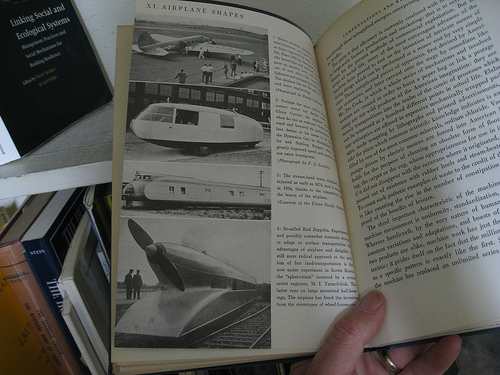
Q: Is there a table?
A: Yes, there is a table.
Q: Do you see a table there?
A: Yes, there is a table.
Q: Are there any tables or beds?
A: Yes, there is a table.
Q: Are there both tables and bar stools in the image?
A: No, there is a table but no bar stools.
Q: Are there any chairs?
A: No, there are no chairs.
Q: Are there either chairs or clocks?
A: No, there are no chairs or clocks.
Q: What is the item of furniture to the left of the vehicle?
A: The piece of furniture is a table.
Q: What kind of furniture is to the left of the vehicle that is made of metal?
A: The piece of furniture is a table.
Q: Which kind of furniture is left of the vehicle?
A: The piece of furniture is a table.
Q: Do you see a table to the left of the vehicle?
A: Yes, there is a table to the left of the vehicle.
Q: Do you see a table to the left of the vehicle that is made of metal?
A: Yes, there is a table to the left of the vehicle.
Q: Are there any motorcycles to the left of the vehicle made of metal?
A: No, there is a table to the left of the vehicle.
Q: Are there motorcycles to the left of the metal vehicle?
A: No, there is a table to the left of the vehicle.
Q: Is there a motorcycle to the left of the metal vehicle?
A: No, there is a table to the left of the vehicle.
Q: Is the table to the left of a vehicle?
A: Yes, the table is to the left of a vehicle.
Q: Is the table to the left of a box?
A: No, the table is to the left of a vehicle.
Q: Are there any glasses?
A: No, there are no glasses.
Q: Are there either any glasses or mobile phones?
A: No, there are no glasses or mobile phones.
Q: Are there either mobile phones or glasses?
A: No, there are no glasses or mobile phones.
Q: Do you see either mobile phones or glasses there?
A: No, there are no glasses or mobile phones.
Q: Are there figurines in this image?
A: No, there are no figurines.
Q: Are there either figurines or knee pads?
A: No, there are no figurines or knee pads.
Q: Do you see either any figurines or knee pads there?
A: No, there are no figurines or knee pads.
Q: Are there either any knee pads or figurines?
A: No, there are no figurines or knee pads.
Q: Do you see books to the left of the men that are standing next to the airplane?
A: Yes, there is a book to the left of the men.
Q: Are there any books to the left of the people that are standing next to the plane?
A: Yes, there is a book to the left of the men.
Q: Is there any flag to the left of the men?
A: No, there is a book to the left of the men.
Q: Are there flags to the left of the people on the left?
A: No, there is a book to the left of the men.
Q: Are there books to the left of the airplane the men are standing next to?
A: Yes, there is a book to the left of the plane.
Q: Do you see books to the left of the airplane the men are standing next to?
A: Yes, there is a book to the left of the plane.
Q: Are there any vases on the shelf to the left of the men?
A: No, there is a book on the shelf.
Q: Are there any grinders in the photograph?
A: No, there are no grinders.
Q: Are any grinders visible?
A: No, there are no grinders.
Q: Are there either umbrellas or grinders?
A: No, there are no grinders or umbrellas.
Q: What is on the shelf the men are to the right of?
A: The book is on the shelf.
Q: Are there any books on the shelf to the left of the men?
A: Yes, there is a book on the shelf.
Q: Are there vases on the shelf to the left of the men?
A: No, there is a book on the shelf.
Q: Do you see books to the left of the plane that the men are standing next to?
A: Yes, there is a book to the left of the airplane.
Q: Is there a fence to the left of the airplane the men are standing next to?
A: No, there is a book to the left of the plane.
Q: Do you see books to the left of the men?
A: Yes, there is a book to the left of the men.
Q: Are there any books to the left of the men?
A: Yes, there is a book to the left of the men.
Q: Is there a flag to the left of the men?
A: No, there is a book to the left of the men.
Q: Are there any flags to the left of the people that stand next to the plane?
A: No, there is a book to the left of the men.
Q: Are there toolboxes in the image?
A: No, there are no toolboxes.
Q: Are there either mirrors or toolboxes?
A: No, there are no toolboxes or mirrors.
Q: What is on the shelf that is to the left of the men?
A: The book is on the shelf.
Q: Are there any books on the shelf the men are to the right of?
A: Yes, there is a book on the shelf.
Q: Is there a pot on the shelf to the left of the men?
A: No, there is a book on the shelf.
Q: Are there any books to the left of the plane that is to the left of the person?
A: Yes, there is a book to the left of the plane.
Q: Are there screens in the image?
A: No, there are no screens.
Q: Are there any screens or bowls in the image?
A: No, there are no screens or bowls.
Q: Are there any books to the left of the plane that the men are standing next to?
A: Yes, there is a book to the left of the airplane.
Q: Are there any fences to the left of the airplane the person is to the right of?
A: No, there is a book to the left of the airplane.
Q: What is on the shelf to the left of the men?
A: The book is on the shelf.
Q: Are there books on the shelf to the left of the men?
A: Yes, there is a book on the shelf.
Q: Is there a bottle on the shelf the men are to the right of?
A: No, there is a book on the shelf.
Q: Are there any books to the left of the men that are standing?
A: Yes, there is a book to the left of the men.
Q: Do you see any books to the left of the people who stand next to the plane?
A: Yes, there is a book to the left of the men.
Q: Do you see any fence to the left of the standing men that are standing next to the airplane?
A: No, there is a book to the left of the men.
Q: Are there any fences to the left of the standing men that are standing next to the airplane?
A: No, there is a book to the left of the men.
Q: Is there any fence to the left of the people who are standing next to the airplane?
A: No, there is a book to the left of the men.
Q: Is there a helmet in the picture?
A: No, there are no helmets.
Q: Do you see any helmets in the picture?
A: No, there are no helmets.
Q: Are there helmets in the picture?
A: No, there are no helmets.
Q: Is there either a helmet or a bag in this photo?
A: No, there are no helmets or bags.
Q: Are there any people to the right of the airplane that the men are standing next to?
A: Yes, there is a person to the right of the plane.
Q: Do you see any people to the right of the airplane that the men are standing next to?
A: Yes, there is a person to the right of the plane.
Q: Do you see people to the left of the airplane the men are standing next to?
A: No, the person is to the right of the plane.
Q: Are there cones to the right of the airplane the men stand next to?
A: No, there is a person to the right of the plane.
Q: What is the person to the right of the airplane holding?
A: The person is holding the book.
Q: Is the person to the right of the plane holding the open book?
A: Yes, the person is holding the book.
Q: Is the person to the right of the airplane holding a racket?
A: No, the person is holding the book.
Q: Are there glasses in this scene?
A: No, there are no glasses.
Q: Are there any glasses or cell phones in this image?
A: No, there are no glasses or cell phones.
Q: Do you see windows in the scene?
A: Yes, there are windows.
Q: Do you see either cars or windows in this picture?
A: Yes, there are windows.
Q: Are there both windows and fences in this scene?
A: No, there are windows but no fences.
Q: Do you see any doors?
A: No, there are no doors.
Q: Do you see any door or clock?
A: No, there are no doors or clocks.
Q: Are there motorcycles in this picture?
A: No, there are no motorcycles.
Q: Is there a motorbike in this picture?
A: No, there are no motorcycles.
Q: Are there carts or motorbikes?
A: No, there are no motorbikes or carts.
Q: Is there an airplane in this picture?
A: Yes, there is an airplane.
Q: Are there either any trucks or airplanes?
A: Yes, there is an airplane.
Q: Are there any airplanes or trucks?
A: Yes, there is an airplane.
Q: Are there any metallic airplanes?
A: Yes, there is a metal airplane.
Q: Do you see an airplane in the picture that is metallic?
A: Yes, there is an airplane that is metallic.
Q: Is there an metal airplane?
A: Yes, there is an airplane that is made of metal.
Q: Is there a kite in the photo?
A: No, there are no kites.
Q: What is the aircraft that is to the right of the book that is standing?
A: The aircraft is an airplane.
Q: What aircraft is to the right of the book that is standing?
A: The aircraft is an airplane.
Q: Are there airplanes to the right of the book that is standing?
A: Yes, there is an airplane to the right of the book.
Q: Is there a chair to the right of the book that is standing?
A: No, there is an airplane to the right of the book.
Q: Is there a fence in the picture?
A: No, there are no fences.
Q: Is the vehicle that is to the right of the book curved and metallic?
A: Yes, the vehicle is curved and metallic.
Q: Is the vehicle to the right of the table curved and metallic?
A: Yes, the vehicle is curved and metallic.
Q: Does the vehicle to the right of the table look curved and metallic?
A: Yes, the vehicle is curved and metallic.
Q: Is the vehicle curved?
A: Yes, the vehicle is curved.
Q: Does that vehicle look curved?
A: Yes, the vehicle is curved.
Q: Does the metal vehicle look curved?
A: Yes, the vehicle is curved.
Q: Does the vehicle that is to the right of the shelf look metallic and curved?
A: Yes, the vehicle is metallic and curved.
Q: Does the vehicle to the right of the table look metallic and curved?
A: Yes, the vehicle is metallic and curved.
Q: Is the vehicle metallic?
A: Yes, the vehicle is metallic.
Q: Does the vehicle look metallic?
A: Yes, the vehicle is metallic.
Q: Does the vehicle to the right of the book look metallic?
A: Yes, the vehicle is metallic.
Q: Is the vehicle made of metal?
A: Yes, the vehicle is made of metal.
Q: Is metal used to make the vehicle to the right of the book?
A: Yes, the vehicle is made of metal.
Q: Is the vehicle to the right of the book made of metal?
A: Yes, the vehicle is made of metal.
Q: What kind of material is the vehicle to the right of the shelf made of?
A: The vehicle is made of metal.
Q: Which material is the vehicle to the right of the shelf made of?
A: The vehicle is made of metal.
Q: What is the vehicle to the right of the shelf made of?
A: The vehicle is made of metal.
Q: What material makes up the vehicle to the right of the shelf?
A: The vehicle is made of metal.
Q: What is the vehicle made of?
A: The vehicle is made of metal.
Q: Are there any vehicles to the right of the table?
A: Yes, there is a vehicle to the right of the table.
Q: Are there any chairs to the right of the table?
A: No, there is a vehicle to the right of the table.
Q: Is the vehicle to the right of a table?
A: Yes, the vehicle is to the right of a table.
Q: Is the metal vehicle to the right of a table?
A: Yes, the vehicle is to the right of a table.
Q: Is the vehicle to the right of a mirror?
A: No, the vehicle is to the right of a table.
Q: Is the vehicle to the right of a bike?
A: No, the vehicle is to the right of the shelf.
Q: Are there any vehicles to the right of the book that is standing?
A: Yes, there is a vehicle to the right of the book.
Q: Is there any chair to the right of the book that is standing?
A: No, there is a vehicle to the right of the book.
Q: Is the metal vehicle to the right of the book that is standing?
A: Yes, the vehicle is to the right of the book.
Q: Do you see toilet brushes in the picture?
A: No, there are no toilet brushes.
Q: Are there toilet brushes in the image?
A: No, there are no toilet brushes.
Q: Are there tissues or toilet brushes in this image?
A: No, there are no toilet brushes or tissues.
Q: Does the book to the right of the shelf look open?
A: Yes, the book is open.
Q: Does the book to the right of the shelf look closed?
A: No, the book is open.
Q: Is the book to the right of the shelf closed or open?
A: The book is open.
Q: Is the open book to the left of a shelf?
A: No, the book is to the right of a shelf.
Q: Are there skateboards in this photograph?
A: No, there are no skateboards.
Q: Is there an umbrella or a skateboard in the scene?
A: No, there are no skateboards or umbrellas.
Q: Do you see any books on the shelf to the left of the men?
A: Yes, there is a book on the shelf.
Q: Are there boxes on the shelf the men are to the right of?
A: No, there is a book on the shelf.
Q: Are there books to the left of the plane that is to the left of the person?
A: Yes, there is a book to the left of the airplane.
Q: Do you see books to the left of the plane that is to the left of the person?
A: Yes, there is a book to the left of the airplane.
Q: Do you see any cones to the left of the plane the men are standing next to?
A: No, there is a book to the left of the airplane.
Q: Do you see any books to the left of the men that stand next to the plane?
A: Yes, there is a book to the left of the men.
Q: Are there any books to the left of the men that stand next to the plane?
A: Yes, there is a book to the left of the men.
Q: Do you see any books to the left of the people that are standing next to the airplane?
A: Yes, there is a book to the left of the men.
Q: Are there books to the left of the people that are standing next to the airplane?
A: Yes, there is a book to the left of the men.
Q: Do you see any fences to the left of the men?
A: No, there is a book to the left of the men.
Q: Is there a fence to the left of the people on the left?
A: No, there is a book to the left of the men.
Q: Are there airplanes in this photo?
A: Yes, there is an airplane.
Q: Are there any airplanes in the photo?
A: Yes, there is an airplane.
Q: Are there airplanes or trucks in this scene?
A: Yes, there is an airplane.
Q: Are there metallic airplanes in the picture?
A: Yes, there is a metal airplane.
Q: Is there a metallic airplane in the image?
A: Yes, there is a metal airplane.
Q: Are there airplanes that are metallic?
A: Yes, there is an airplane that is metallic.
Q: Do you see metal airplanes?
A: Yes, there is an airplane that is made of metal.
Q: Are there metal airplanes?
A: Yes, there is an airplane that is made of metal.